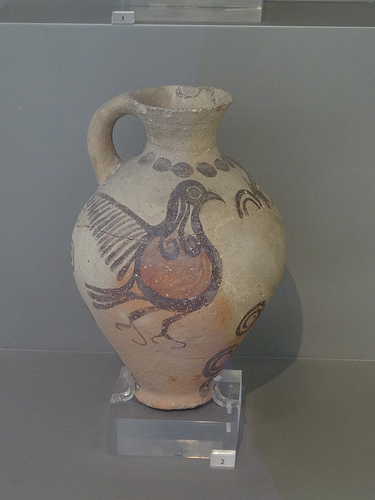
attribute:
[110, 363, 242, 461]
base — clear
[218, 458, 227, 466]
2 — black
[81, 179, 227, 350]
bird — painted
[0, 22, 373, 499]
display — grey, gray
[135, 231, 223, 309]
belly — red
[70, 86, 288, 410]
pot — clay, old, painted, handmade, upright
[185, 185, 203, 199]
eye — little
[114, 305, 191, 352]
legs — thin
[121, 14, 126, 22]
1 — black